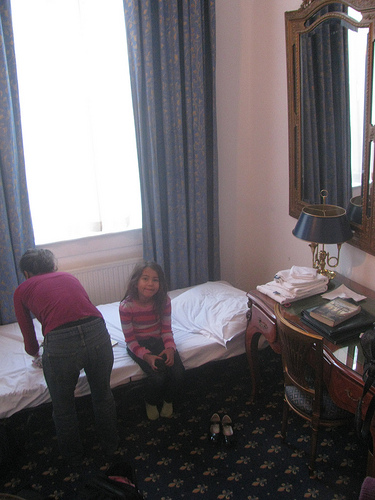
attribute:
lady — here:
[11, 246, 121, 466]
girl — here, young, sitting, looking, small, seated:
[117, 256, 185, 427]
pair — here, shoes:
[207, 410, 239, 450]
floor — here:
[2, 332, 375, 493]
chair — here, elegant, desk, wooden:
[276, 307, 365, 464]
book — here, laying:
[308, 294, 362, 327]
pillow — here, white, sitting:
[167, 273, 263, 350]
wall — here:
[209, 1, 373, 298]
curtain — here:
[121, 0, 226, 322]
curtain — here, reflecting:
[2, 0, 47, 323]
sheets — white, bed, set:
[2, 273, 264, 410]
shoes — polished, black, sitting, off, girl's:
[203, 410, 238, 450]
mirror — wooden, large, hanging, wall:
[281, 0, 374, 258]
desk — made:
[237, 267, 374, 488]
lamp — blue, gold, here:
[293, 184, 361, 289]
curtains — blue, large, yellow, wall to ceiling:
[2, 0, 220, 328]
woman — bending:
[12, 247, 123, 477]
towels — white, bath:
[253, 266, 330, 306]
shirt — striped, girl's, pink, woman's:
[117, 295, 175, 359]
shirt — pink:
[12, 266, 105, 357]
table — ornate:
[240, 262, 374, 475]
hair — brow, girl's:
[120, 255, 170, 314]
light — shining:
[10, 1, 148, 245]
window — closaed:
[8, 0, 157, 274]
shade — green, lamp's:
[289, 200, 355, 245]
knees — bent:
[146, 363, 186, 383]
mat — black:
[6, 339, 374, 494]